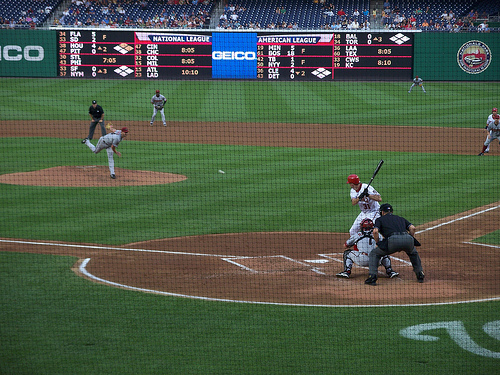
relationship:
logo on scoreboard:
[216, 48, 257, 68] [51, 21, 419, 84]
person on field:
[342, 171, 387, 251] [4, 74, 493, 367]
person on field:
[77, 121, 129, 181] [4, 74, 493, 367]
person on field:
[355, 199, 427, 287] [4, 74, 493, 367]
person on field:
[144, 87, 169, 127] [4, 74, 493, 367]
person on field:
[405, 71, 427, 95] [4, 74, 493, 367]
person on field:
[475, 103, 498, 155] [4, 74, 493, 367]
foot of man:
[81, 135, 87, 143] [84, 86, 112, 160]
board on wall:
[60, 27, 411, 83] [2, 26, 497, 78]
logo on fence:
[216, 48, 257, 68] [212, 50, 256, 60]